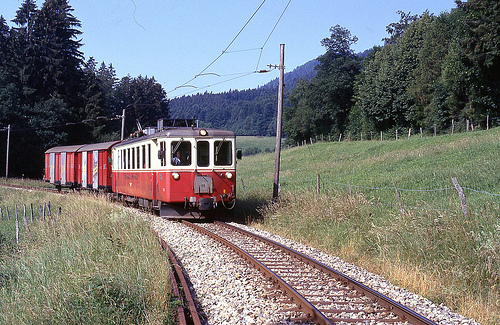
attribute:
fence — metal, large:
[283, 115, 495, 145]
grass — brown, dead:
[361, 214, 484, 290]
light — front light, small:
[224, 169, 233, 181]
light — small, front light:
[171, 172, 181, 179]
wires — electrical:
[165, 67, 272, 82]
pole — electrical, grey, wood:
[265, 40, 301, 207]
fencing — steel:
[266, 114, 499, 156]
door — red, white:
[138, 135, 190, 199]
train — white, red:
[22, 100, 283, 238]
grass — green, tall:
[354, 151, 494, 278]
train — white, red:
[33, 110, 243, 219]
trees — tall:
[314, 53, 462, 134]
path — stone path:
[167, 214, 467, 324]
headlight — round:
[169, 171, 181, 183]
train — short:
[50, 110, 250, 223]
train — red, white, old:
[36, 120, 242, 221]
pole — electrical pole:
[272, 42, 285, 202]